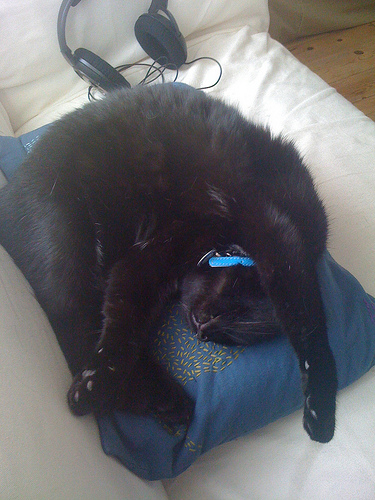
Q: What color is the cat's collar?
A: Blue.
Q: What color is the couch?
A: White.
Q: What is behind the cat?
A: Headphones.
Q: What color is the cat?
A: Black.